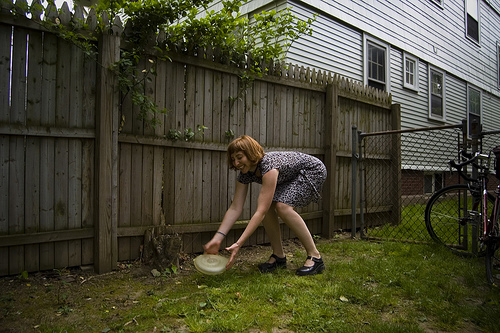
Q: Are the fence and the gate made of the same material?
A: No, the fence is made of wood and the gate is made of metal.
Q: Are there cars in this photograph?
A: No, there are no cars.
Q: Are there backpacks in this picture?
A: Yes, there is a backpack.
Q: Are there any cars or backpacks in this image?
A: Yes, there is a backpack.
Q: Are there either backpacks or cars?
A: Yes, there is a backpack.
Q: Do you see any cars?
A: No, there are no cars.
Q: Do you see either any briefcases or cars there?
A: No, there are no cars or briefcases.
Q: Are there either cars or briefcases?
A: No, there are no cars or briefcases.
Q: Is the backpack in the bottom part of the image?
A: Yes, the backpack is in the bottom of the image.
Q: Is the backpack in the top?
A: No, the backpack is in the bottom of the image.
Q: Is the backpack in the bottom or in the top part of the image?
A: The backpack is in the bottom of the image.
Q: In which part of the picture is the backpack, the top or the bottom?
A: The backpack is in the bottom of the image.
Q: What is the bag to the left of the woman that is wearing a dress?
A: The bag is a backpack.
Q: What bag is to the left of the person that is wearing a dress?
A: The bag is a backpack.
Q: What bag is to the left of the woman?
A: The bag is a backpack.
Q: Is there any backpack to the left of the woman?
A: Yes, there is a backpack to the left of the woman.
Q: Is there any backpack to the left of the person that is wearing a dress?
A: Yes, there is a backpack to the left of the woman.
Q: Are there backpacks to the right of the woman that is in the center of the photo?
A: No, the backpack is to the left of the woman.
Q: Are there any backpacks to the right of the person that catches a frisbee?
A: No, the backpack is to the left of the woman.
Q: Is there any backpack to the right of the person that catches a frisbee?
A: No, the backpack is to the left of the woman.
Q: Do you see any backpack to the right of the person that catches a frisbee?
A: No, the backpack is to the left of the woman.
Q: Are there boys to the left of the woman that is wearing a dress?
A: No, there is a backpack to the left of the woman.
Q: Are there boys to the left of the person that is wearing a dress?
A: No, there is a backpack to the left of the woman.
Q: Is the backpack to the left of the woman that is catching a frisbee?
A: Yes, the backpack is to the left of the woman.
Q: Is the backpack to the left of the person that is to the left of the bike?
A: Yes, the backpack is to the left of the woman.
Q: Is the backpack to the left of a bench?
A: No, the backpack is to the left of the woman.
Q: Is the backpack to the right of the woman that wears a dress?
A: No, the backpack is to the left of the woman.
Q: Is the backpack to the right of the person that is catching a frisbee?
A: No, the backpack is to the left of the woman.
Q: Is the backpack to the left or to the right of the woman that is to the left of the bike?
A: The backpack is to the left of the woman.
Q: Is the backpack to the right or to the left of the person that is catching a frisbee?
A: The backpack is to the left of the woman.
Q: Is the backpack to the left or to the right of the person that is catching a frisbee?
A: The backpack is to the left of the woman.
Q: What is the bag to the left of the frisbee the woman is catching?
A: The bag is a backpack.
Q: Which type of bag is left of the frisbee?
A: The bag is a backpack.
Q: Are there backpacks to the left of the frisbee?
A: Yes, there is a backpack to the left of the frisbee.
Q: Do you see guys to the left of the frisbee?
A: No, there is a backpack to the left of the frisbee.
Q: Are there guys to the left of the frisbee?
A: No, there is a backpack to the left of the frisbee.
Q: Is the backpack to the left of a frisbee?
A: Yes, the backpack is to the left of a frisbee.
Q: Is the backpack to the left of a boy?
A: No, the backpack is to the left of a frisbee.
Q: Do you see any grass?
A: Yes, there is grass.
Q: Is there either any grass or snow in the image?
A: Yes, there is grass.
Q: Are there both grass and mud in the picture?
A: No, there is grass but no mud.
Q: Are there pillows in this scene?
A: No, there are no pillows.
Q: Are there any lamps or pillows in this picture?
A: No, there are no pillows or lamps.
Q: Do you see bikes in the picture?
A: Yes, there is a bike.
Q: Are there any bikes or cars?
A: Yes, there is a bike.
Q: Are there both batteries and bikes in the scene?
A: No, there is a bike but no batteries.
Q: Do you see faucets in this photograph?
A: No, there are no faucets.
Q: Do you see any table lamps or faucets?
A: No, there are no faucets or table lamps.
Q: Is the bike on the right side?
A: Yes, the bike is on the right of the image.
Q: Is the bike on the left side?
A: No, the bike is on the right of the image.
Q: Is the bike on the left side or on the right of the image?
A: The bike is on the right of the image.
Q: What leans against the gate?
A: The bike leans against the gate.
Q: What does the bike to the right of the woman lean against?
A: The bike leans against the gate.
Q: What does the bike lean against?
A: The bike leans against the gate.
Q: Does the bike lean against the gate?
A: Yes, the bike leans against the gate.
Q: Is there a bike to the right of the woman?
A: Yes, there is a bike to the right of the woman.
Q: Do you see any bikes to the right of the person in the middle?
A: Yes, there is a bike to the right of the woman.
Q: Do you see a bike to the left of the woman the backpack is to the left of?
A: No, the bike is to the right of the woman.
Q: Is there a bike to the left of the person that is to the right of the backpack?
A: No, the bike is to the right of the woman.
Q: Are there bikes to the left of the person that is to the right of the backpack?
A: No, the bike is to the right of the woman.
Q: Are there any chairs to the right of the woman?
A: No, there is a bike to the right of the woman.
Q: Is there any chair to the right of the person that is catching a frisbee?
A: No, there is a bike to the right of the woman.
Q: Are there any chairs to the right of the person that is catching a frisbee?
A: No, there is a bike to the right of the woman.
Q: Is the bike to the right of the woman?
A: Yes, the bike is to the right of the woman.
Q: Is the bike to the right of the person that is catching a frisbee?
A: Yes, the bike is to the right of the woman.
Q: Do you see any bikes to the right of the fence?
A: Yes, there is a bike to the right of the fence.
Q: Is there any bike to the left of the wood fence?
A: No, the bike is to the right of the fence.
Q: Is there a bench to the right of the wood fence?
A: No, there is a bike to the right of the fence.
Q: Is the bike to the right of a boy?
A: No, the bike is to the right of a fence.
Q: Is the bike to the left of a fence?
A: No, the bike is to the right of a fence.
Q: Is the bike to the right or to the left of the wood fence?
A: The bike is to the right of the fence.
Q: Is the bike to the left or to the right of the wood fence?
A: The bike is to the right of the fence.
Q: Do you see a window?
A: Yes, there is a window.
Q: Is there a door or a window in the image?
A: Yes, there is a window.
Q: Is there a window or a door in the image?
A: Yes, there is a window.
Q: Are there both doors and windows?
A: No, there is a window but no doors.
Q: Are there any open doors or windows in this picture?
A: Yes, there is an open window.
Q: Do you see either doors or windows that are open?
A: Yes, the window is open.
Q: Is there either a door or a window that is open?
A: Yes, the window is open.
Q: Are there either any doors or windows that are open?
A: Yes, the window is open.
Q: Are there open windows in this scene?
A: Yes, there is an open window.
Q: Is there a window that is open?
A: Yes, there is a window that is open.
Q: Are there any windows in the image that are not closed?
A: Yes, there is a open window.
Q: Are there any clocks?
A: No, there are no clocks.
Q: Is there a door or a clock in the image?
A: No, there are no clocks or doors.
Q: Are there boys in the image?
A: No, there are no boys.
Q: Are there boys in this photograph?
A: No, there are no boys.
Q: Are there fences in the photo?
A: Yes, there is a fence.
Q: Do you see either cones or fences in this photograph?
A: Yes, there is a fence.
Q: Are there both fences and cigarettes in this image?
A: No, there is a fence but no cigarettes.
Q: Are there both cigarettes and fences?
A: No, there is a fence but no cigarettes.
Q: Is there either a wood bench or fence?
A: Yes, there is a wood fence.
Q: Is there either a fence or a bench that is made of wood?
A: Yes, the fence is made of wood.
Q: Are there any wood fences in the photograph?
A: Yes, there is a wood fence.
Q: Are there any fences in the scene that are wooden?
A: Yes, there is a fence that is wooden.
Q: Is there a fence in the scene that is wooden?
A: Yes, there is a fence that is wooden.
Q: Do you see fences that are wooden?
A: Yes, there is a fence that is wooden.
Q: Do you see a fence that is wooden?
A: Yes, there is a fence that is wooden.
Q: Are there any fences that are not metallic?
A: Yes, there is a wooden fence.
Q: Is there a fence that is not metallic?
A: Yes, there is a wooden fence.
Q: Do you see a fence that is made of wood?
A: Yes, there is a fence that is made of wood.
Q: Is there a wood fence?
A: Yes, there is a fence that is made of wood.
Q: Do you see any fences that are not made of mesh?
A: Yes, there is a fence that is made of wood.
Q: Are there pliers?
A: No, there are no pliers.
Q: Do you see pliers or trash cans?
A: No, there are no pliers or trash cans.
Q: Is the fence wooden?
A: Yes, the fence is wooden.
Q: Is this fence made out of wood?
A: Yes, the fence is made of wood.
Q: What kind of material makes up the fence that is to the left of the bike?
A: The fence is made of wood.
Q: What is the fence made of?
A: The fence is made of wood.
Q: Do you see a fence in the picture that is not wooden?
A: No, there is a fence but it is wooden.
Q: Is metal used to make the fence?
A: No, the fence is made of wood.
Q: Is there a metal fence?
A: No, there is a fence but it is made of wood.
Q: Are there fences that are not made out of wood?
A: No, there is a fence but it is made of wood.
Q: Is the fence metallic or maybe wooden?
A: The fence is wooden.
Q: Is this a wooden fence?
A: Yes, this is a wooden fence.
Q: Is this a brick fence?
A: No, this is a wooden fence.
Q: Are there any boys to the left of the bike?
A: No, there is a fence to the left of the bike.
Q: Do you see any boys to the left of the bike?
A: No, there is a fence to the left of the bike.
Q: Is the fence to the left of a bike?
A: Yes, the fence is to the left of a bike.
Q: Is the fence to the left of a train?
A: No, the fence is to the left of a bike.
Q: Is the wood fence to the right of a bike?
A: No, the fence is to the left of a bike.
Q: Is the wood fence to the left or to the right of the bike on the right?
A: The fence is to the left of the bike.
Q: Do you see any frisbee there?
A: Yes, there is a frisbee.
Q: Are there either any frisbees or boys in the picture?
A: Yes, there is a frisbee.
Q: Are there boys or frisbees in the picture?
A: Yes, there is a frisbee.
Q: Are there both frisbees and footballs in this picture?
A: No, there is a frisbee but no footballs.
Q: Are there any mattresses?
A: No, there are no mattresses.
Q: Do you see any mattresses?
A: No, there are no mattresses.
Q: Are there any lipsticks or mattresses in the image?
A: No, there are no mattresses or lipsticks.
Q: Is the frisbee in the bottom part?
A: Yes, the frisbee is in the bottom of the image.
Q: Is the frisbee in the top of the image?
A: No, the frisbee is in the bottom of the image.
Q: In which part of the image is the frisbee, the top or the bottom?
A: The frisbee is in the bottom of the image.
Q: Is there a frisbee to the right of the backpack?
A: Yes, there is a frisbee to the right of the backpack.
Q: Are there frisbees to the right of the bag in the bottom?
A: Yes, there is a frisbee to the right of the backpack.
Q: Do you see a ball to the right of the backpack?
A: No, there is a frisbee to the right of the backpack.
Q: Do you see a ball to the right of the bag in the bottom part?
A: No, there is a frisbee to the right of the backpack.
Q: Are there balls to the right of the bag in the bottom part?
A: No, there is a frisbee to the right of the backpack.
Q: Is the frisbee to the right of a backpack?
A: Yes, the frisbee is to the right of a backpack.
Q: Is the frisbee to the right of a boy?
A: No, the frisbee is to the right of a backpack.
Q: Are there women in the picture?
A: Yes, there is a woman.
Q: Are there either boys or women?
A: Yes, there is a woman.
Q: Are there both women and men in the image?
A: No, there is a woman but no men.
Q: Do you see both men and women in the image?
A: No, there is a woman but no men.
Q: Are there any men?
A: No, there are no men.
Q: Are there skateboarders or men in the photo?
A: No, there are no men or skateboarders.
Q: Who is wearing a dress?
A: The woman is wearing a dress.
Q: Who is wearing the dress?
A: The woman is wearing a dress.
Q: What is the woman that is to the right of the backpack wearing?
A: The woman is wearing a dress.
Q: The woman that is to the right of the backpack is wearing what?
A: The woman is wearing a dress.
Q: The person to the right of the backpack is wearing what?
A: The woman is wearing a dress.